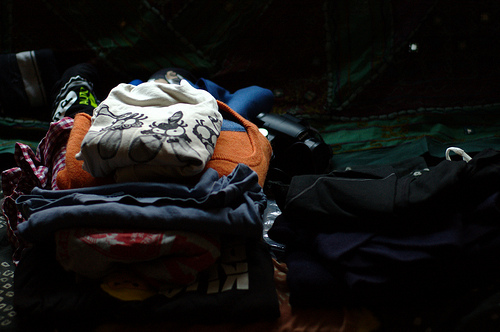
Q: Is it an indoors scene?
A: Yes, it is indoors.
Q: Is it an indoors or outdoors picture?
A: It is indoors.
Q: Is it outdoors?
A: No, it is indoors.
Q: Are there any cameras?
A: Yes, there is a camera.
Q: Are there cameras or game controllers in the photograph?
A: Yes, there is a camera.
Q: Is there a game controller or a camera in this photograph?
A: Yes, there is a camera.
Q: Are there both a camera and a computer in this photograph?
A: No, there is a camera but no computers.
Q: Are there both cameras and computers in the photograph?
A: No, there is a camera but no computers.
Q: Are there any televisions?
A: No, there are no televisions.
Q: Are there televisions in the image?
A: No, there are no televisions.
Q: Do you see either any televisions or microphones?
A: No, there are no televisions or microphones.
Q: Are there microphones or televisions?
A: No, there are no televisions or microphones.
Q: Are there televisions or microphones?
A: No, there are no televisions or microphones.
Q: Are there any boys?
A: No, there are no boys.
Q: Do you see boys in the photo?
A: No, there are no boys.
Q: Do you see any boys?
A: No, there are no boys.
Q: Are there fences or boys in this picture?
A: No, there are no boys or fences.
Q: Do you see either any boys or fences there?
A: No, there are no boys or fences.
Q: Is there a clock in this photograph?
A: No, there are no clocks.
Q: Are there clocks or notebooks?
A: No, there are no clocks or notebooks.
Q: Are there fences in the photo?
A: No, there are no fences.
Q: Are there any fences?
A: No, there are no fences.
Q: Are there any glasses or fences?
A: No, there are no fences or glasses.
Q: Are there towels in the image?
A: Yes, there is a towel.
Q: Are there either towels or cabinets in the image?
A: Yes, there is a towel.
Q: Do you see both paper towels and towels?
A: No, there is a towel but no paper towels.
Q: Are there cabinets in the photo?
A: No, there are no cabinets.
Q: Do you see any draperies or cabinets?
A: No, there are no cabinets or draperies.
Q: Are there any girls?
A: No, there are no girls.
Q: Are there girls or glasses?
A: No, there are no girls or glasses.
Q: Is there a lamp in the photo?
A: No, there are no lamps.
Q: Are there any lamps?
A: No, there are no lamps.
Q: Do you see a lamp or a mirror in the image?
A: No, there are no lamps or mirrors.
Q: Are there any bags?
A: Yes, there is a bag.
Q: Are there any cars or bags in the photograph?
A: Yes, there is a bag.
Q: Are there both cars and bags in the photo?
A: No, there is a bag but no cars.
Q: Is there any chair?
A: No, there are no chairs.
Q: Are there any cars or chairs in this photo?
A: No, there are no chairs or cars.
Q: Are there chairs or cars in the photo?
A: No, there are no chairs or cars.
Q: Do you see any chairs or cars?
A: No, there are no chairs or cars.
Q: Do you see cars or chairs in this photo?
A: No, there are no chairs or cars.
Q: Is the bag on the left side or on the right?
A: The bag is on the right of the image.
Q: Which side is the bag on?
A: The bag is on the right of the image.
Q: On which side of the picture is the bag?
A: The bag is on the right of the image.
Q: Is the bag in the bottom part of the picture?
A: No, the bag is in the top of the image.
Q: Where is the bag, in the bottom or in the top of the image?
A: The bag is in the top of the image.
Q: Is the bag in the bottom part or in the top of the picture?
A: The bag is in the top of the image.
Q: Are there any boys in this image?
A: No, there are no boys.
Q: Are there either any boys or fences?
A: No, there are no boys or fences.